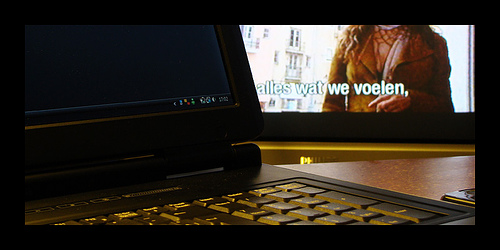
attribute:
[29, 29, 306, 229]
laptop —  black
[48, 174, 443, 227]
keyboard — black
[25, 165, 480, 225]
keypad —  number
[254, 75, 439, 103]
words — white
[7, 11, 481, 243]
laptop — black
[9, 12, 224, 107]
screen — black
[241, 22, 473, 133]
television — on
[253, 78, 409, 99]
lettering —  white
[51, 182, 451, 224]
keyboard — black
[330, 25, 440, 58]
brown hair — long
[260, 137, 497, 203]
countertop — brown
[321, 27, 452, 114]
jacket — green,  brown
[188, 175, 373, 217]
keyboard —  lap top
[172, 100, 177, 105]
icon — colorful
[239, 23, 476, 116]
screen —  tv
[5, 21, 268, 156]
screen — computer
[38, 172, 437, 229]
keyboard — black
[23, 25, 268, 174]
screen — computer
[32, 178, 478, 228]
keyboard — black